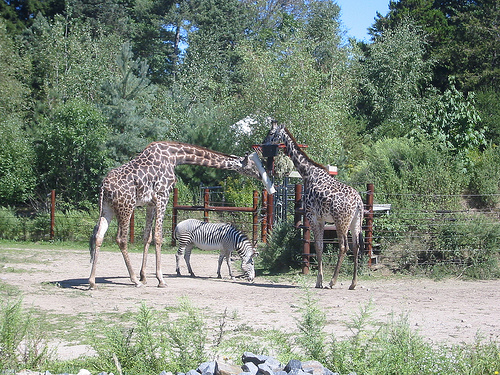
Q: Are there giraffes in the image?
A: Yes, there are giraffes.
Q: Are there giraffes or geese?
A: Yes, there are giraffes.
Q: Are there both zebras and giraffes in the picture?
A: Yes, there are both giraffes and a zebra.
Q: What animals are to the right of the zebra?
A: The animals are giraffes.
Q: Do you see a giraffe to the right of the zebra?
A: Yes, there are giraffes to the right of the zebra.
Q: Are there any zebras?
A: Yes, there is a zebra.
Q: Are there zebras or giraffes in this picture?
A: Yes, there is a zebra.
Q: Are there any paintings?
A: No, there are no paintings.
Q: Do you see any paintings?
A: No, there are no paintings.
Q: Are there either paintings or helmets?
A: No, there are no paintings or helmets.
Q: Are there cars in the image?
A: No, there are no cars.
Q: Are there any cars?
A: No, there are no cars.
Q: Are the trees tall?
A: Yes, the trees are tall.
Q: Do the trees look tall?
A: Yes, the trees are tall.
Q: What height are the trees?
A: The trees are tall.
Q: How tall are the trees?
A: The trees are tall.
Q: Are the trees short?
A: No, the trees are tall.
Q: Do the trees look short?
A: No, the trees are tall.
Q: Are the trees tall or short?
A: The trees are tall.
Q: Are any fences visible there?
A: Yes, there is a fence.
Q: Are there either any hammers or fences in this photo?
A: Yes, there is a fence.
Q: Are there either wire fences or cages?
A: Yes, there is a wire fence.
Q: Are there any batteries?
A: No, there are no batteries.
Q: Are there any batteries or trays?
A: No, there are no batteries or trays.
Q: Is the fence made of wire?
A: Yes, the fence is made of wire.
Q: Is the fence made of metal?
A: No, the fence is made of wire.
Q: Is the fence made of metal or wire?
A: The fence is made of wire.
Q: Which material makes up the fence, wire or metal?
A: The fence is made of wire.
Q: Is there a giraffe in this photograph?
A: Yes, there are giraffes.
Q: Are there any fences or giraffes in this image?
A: Yes, there are giraffes.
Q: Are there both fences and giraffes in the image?
A: Yes, there are both giraffes and a fence.